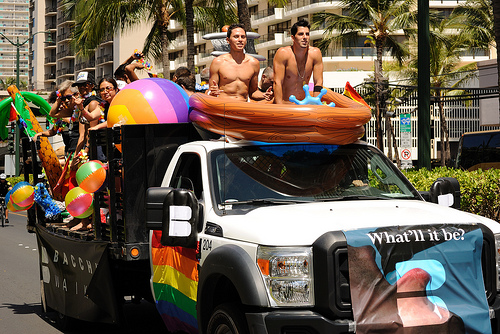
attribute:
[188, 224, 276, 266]
204 — black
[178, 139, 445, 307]
truck — pickup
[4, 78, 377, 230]
beach toys — inflatable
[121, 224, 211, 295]
flag — rainbow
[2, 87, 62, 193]
palm tree — inflatable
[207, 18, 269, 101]
man — topless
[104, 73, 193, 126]
ball — rainbow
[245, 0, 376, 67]
apartment buildings — multi story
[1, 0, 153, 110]
apartment buildings — multi story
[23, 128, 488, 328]
truck — half ton, white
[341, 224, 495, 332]
corporate logo — big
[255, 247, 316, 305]
headlight — left side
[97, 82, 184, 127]
ball — beach, multi color, large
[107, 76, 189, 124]
beach ball — multicolored, blow up, large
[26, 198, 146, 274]
bed — black